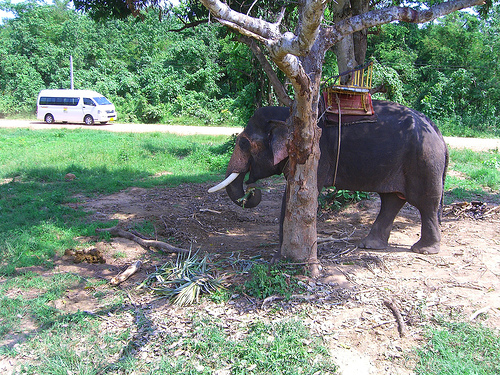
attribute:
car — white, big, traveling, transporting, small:
[35, 86, 119, 127]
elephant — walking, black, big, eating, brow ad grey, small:
[208, 98, 451, 257]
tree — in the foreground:
[70, 2, 495, 262]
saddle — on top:
[319, 61, 376, 119]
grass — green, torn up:
[3, 126, 500, 374]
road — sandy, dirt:
[1, 117, 500, 152]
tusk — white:
[204, 168, 240, 196]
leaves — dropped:
[248, 262, 303, 300]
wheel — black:
[84, 114, 94, 124]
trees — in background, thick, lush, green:
[2, 2, 499, 140]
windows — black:
[83, 95, 98, 107]